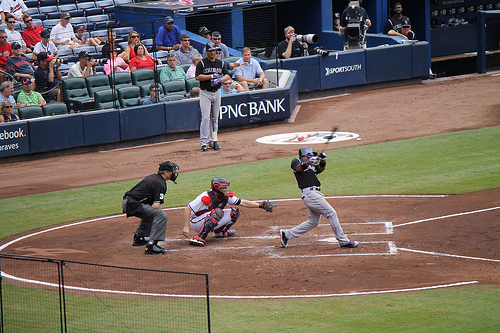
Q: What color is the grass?
A: Green.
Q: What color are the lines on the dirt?
A: White.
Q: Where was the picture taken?
A: At a ballpark.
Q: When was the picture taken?
A: Daytime.